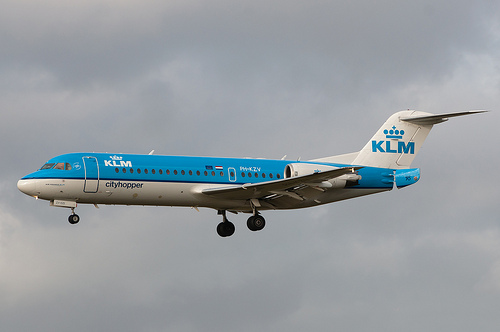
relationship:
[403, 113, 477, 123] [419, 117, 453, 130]
rudder has elevators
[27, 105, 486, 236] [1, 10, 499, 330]
airplane in sky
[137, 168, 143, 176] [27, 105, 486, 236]
windows on airplane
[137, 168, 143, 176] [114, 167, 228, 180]
windows in row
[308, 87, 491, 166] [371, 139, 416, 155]
tail has klm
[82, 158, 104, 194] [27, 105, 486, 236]
door on airplane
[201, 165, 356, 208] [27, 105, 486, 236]
wing on airplane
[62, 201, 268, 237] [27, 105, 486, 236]
gear on airplane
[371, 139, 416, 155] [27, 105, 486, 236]
klm on airplane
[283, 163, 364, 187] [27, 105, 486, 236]
engine on airplane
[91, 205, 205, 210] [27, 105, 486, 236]
flags on airplane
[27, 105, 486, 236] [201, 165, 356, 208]
airplane has wing